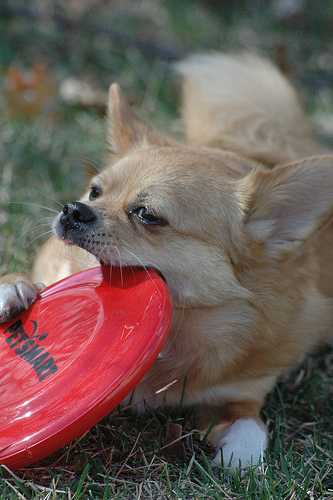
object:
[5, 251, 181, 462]
frisbee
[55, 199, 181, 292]
dogs mouth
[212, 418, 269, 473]
paw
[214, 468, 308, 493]
grass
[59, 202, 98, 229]
black nose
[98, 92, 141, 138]
right ear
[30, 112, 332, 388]
dog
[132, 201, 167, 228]
eye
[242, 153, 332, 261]
ear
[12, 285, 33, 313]
claw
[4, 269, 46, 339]
paw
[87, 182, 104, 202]
eye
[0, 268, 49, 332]
dog's paw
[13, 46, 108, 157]
grass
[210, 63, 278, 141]
tail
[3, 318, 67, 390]
word